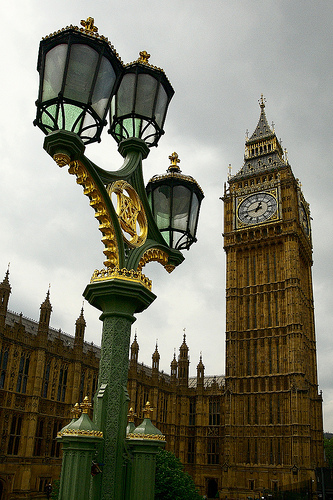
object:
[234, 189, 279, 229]
clock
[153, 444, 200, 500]
bush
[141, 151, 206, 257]
lights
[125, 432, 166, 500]
pillars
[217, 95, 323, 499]
building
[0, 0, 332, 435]
sky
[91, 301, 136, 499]
pole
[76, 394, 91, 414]
crosses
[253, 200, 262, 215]
hands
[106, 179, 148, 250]
circle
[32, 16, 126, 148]
lamp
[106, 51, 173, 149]
lamp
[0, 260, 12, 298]
spires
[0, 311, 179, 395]
roof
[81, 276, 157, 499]
pillar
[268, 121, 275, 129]
crosses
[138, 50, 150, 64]
crosses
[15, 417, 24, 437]
window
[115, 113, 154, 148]
bulbs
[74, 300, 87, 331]
steeple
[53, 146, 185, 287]
decorations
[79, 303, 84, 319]
point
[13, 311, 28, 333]
spikes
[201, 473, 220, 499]
door